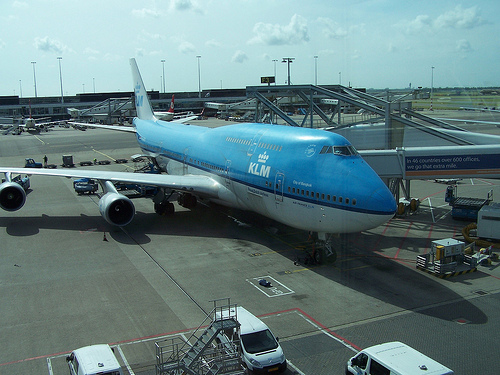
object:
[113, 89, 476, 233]
airplane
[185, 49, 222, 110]
light poles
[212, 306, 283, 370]
van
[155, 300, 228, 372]
staircase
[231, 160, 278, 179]
klm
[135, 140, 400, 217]
stripe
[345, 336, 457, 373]
van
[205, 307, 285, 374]
van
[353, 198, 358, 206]
window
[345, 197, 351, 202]
window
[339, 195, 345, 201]
window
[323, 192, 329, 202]
window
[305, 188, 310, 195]
window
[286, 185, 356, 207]
row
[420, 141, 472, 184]
ground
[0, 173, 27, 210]
engine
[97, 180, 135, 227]
engine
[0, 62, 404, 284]
airplane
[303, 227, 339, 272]
landing gear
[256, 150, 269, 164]
crown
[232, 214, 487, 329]
shadow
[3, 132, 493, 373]
tarmac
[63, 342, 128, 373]
van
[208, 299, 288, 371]
van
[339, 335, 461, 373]
van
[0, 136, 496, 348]
tarmac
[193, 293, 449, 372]
vans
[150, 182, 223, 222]
gear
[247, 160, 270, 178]
klm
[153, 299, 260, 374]
platform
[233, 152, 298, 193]
logo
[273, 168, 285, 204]
door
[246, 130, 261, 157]
door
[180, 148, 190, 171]
door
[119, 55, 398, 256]
airplane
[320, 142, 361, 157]
windows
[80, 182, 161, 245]
engine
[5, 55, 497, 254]
plane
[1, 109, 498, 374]
tarmac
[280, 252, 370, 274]
line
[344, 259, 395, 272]
line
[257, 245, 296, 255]
line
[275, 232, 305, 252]
line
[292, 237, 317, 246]
line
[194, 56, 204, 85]
light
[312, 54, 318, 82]
light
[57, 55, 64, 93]
light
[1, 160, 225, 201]
wing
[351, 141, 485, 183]
jetbridge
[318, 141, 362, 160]
cockpit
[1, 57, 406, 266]
plane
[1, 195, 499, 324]
shadow